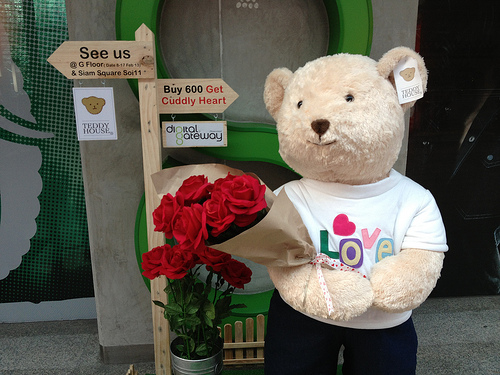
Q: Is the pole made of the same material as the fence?
A: Yes, both the pole and the fence are made of wood.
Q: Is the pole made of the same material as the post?
A: Yes, both the pole and the post are made of wood.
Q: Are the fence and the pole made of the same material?
A: Yes, both the fence and the pole are made of wood.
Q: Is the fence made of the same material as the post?
A: Yes, both the fence and the post are made of wood.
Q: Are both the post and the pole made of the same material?
A: Yes, both the post and the pole are made of wood.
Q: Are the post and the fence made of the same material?
A: Yes, both the post and the fence are made of wood.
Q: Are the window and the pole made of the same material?
A: No, the window is made of glass and the pole is made of wood.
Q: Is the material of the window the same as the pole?
A: No, the window is made of glass and the pole is made of wood.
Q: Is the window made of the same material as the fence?
A: No, the window is made of glass and the fence is made of wood.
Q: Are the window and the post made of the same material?
A: No, the window is made of glass and the post is made of wood.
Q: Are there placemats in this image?
A: No, there are no placemats.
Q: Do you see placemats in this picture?
A: No, there are no placemats.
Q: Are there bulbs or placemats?
A: No, there are no placemats or bulbs.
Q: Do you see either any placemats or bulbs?
A: No, there are no placemats or bulbs.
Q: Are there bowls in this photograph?
A: No, there are no bowls.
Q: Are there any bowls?
A: No, there are no bowls.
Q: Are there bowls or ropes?
A: No, there are no bowls or ropes.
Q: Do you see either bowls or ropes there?
A: No, there are no bowls or ropes.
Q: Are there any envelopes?
A: No, there are no envelopes.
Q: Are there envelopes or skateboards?
A: No, there are no envelopes or skateboards.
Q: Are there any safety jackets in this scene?
A: No, there are no safety jackets.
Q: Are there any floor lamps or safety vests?
A: No, there are no safety vests or floor lamps.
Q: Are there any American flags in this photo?
A: No, there are no American flags.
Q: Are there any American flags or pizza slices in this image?
A: No, there are no American flags or pizza slices.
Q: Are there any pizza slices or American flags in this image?
A: No, there are no American flags or pizza slices.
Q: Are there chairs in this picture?
A: No, there are no chairs.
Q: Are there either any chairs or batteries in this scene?
A: No, there are no chairs or batteries.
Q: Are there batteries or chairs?
A: No, there are no chairs or batteries.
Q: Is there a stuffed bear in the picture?
A: Yes, there is a stuffed bear.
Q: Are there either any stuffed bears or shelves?
A: Yes, there is a stuffed bear.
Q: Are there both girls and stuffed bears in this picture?
A: No, there is a stuffed bear but no girls.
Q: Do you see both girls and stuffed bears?
A: No, there is a stuffed bear but no girls.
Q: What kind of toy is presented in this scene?
A: The toy is a stuffed bear.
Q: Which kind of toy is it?
A: The toy is a stuffed bear.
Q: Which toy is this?
A: That is a stuffed bear.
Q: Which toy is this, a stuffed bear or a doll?
A: That is a stuffed bear.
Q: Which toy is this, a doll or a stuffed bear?
A: That is a stuffed bear.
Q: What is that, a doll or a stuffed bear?
A: That is a stuffed bear.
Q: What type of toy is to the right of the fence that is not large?
A: The toy is a stuffed bear.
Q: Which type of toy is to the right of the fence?
A: The toy is a stuffed bear.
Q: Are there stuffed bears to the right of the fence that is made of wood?
A: Yes, there is a stuffed bear to the right of the fence.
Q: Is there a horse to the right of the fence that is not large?
A: No, there is a stuffed bear to the right of the fence.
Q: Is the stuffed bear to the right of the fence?
A: Yes, the stuffed bear is to the right of the fence.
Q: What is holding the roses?
A: The stuffed bear is holding the roses.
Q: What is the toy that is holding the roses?
A: The toy is a stuffed bear.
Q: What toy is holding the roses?
A: The toy is a stuffed bear.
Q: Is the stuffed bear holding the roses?
A: Yes, the stuffed bear is holding the roses.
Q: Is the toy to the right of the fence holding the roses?
A: Yes, the stuffed bear is holding the roses.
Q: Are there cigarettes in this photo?
A: No, there are no cigarettes.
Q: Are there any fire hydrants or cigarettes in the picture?
A: No, there are no cigarettes or fire hydrants.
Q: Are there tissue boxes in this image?
A: No, there are no tissue boxes.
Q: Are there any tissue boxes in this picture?
A: No, there are no tissue boxes.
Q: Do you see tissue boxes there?
A: No, there are no tissue boxes.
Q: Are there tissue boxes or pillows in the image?
A: No, there are no tissue boxes or pillows.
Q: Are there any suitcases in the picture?
A: No, there are no suitcases.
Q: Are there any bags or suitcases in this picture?
A: No, there are no suitcases or bags.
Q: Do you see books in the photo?
A: No, there are no books.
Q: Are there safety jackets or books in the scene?
A: No, there are no books or safety jackets.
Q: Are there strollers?
A: No, there are no strollers.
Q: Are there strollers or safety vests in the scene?
A: No, there are no strollers or safety vests.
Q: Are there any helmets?
A: No, there are no helmets.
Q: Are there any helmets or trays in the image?
A: No, there are no helmets or trays.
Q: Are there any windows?
A: Yes, there is a window.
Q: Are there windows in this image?
A: Yes, there is a window.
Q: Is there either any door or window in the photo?
A: Yes, there is a window.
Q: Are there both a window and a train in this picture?
A: No, there is a window but no trains.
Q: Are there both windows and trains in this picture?
A: No, there is a window but no trains.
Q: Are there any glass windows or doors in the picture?
A: Yes, there is a glass window.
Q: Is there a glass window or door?
A: Yes, there is a glass window.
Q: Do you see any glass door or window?
A: Yes, there is a glass window.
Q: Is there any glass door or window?
A: Yes, there is a glass window.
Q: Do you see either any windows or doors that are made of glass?
A: Yes, the window is made of glass.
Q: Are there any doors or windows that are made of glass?
A: Yes, the window is made of glass.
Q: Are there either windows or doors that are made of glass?
A: Yes, the window is made of glass.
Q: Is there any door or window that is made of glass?
A: Yes, the window is made of glass.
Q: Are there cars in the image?
A: No, there are no cars.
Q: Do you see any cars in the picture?
A: No, there are no cars.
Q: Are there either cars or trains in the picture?
A: No, there are no cars or trains.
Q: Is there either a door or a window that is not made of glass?
A: No, there is a window but it is made of glass.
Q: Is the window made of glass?
A: Yes, the window is made of glass.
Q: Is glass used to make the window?
A: Yes, the window is made of glass.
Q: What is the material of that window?
A: The window is made of glass.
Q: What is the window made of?
A: The window is made of glass.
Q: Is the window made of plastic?
A: No, the window is made of glass.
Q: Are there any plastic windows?
A: No, there is a window but it is made of glass.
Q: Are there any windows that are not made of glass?
A: No, there is a window but it is made of glass.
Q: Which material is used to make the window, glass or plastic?
A: The window is made of glass.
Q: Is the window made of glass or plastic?
A: The window is made of glass.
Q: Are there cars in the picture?
A: No, there are no cars.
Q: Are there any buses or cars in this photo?
A: No, there are no cars or buses.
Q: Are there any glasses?
A: No, there are no glasses.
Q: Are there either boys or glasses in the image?
A: No, there are no glasses or boys.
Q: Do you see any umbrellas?
A: No, there are no umbrellas.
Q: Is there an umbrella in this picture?
A: No, there are no umbrellas.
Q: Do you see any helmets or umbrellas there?
A: No, there are no umbrellas or helmets.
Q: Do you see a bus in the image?
A: No, there are no buses.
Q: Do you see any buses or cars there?
A: No, there are no buses or cars.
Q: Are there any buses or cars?
A: No, there are no buses or cars.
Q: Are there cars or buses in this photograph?
A: No, there are no buses or cars.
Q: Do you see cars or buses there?
A: No, there are no buses or cars.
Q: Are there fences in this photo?
A: Yes, there is a fence.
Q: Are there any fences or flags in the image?
A: Yes, there is a fence.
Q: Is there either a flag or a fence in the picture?
A: Yes, there is a fence.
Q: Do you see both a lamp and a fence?
A: No, there is a fence but no lamps.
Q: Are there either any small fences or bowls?
A: Yes, there is a small fence.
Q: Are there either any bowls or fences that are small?
A: Yes, the fence is small.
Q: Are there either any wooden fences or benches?
A: Yes, there is a wood fence.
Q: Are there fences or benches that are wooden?
A: Yes, the fence is wooden.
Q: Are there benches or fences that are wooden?
A: Yes, the fence is wooden.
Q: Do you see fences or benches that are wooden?
A: Yes, the fence is wooden.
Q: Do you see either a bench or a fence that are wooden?
A: Yes, the fence is wooden.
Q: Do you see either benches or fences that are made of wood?
A: Yes, the fence is made of wood.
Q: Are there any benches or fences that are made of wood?
A: Yes, the fence is made of wood.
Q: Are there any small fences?
A: Yes, there is a small fence.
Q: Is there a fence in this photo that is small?
A: Yes, there is a fence that is small.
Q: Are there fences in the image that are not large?
A: Yes, there is a small fence.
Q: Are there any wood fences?
A: Yes, there is a wood fence.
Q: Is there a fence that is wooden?
A: Yes, there is a fence that is wooden.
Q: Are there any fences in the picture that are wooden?
A: Yes, there is a fence that is wooden.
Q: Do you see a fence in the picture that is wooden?
A: Yes, there is a fence that is wooden.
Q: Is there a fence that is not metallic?
A: Yes, there is a wooden fence.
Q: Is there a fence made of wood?
A: Yes, there is a fence that is made of wood.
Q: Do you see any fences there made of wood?
A: Yes, there is a fence that is made of wood.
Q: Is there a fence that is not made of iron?
A: Yes, there is a fence that is made of wood.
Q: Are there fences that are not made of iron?
A: Yes, there is a fence that is made of wood.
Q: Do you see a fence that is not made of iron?
A: Yes, there is a fence that is made of wood.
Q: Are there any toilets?
A: No, there are no toilets.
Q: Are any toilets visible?
A: No, there are no toilets.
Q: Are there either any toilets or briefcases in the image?
A: No, there are no toilets or briefcases.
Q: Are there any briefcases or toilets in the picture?
A: No, there are no toilets or briefcases.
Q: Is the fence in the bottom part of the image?
A: Yes, the fence is in the bottom of the image.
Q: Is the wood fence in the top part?
A: No, the fence is in the bottom of the image.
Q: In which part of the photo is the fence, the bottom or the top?
A: The fence is in the bottom of the image.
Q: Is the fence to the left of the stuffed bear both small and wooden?
A: Yes, the fence is small and wooden.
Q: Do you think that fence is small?
A: Yes, the fence is small.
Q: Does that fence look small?
A: Yes, the fence is small.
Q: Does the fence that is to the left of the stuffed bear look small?
A: Yes, the fence is small.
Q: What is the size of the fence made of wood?
A: The fence is small.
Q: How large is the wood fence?
A: The fence is small.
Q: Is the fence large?
A: No, the fence is small.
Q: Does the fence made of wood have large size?
A: No, the fence is small.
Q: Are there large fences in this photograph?
A: No, there is a fence but it is small.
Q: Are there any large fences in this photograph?
A: No, there is a fence but it is small.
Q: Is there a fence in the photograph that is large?
A: No, there is a fence but it is small.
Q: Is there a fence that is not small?
A: No, there is a fence but it is small.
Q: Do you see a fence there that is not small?
A: No, there is a fence but it is small.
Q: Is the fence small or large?
A: The fence is small.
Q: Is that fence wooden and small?
A: Yes, the fence is wooden and small.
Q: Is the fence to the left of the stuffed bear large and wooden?
A: No, the fence is wooden but small.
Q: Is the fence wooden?
A: Yes, the fence is wooden.